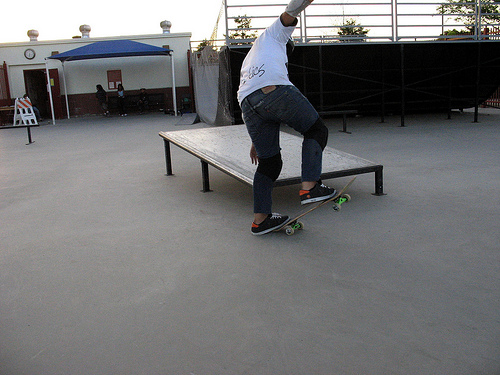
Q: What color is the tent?
A: Blue.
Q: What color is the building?
A: Tan.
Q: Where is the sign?
A: By the tent.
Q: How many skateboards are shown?
A: One.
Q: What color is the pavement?
A: Gray.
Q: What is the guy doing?
A: Skateboarding.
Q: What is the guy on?
A: Skateboard.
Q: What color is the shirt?
A: White.